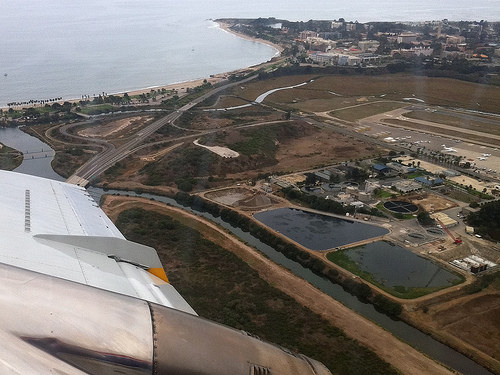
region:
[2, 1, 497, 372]
View from an airplane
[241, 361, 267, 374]
Vent on airplane wing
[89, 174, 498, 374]
Creek running down the city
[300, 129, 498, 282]
Group of buildings on the ground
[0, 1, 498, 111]
Large body of water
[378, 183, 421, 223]
Small black and white circle landing pad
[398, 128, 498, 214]
Group of trees on the ground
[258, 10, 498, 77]
Group of houses and buildings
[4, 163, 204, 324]
White wing of airplane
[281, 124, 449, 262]
Buildings on the ground.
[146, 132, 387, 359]
Water on the ground.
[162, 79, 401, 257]
Trees on the ground.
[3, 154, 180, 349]
Plane in the air.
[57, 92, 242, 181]
Road on the ground.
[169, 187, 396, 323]
Trees by the water.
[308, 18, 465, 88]
Town in the background.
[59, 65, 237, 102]
Beach by the water.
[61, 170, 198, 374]
Wing on the plane.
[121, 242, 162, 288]
Yellow part of the plane.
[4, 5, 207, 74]
calm water with no waves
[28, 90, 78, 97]
small waves near shore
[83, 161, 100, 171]
section of road for automobiles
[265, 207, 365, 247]
large pool of water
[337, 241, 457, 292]
large rectangular pool of water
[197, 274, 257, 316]
patch of earth missing grass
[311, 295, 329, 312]
dirt path near field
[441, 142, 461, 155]
parked airplane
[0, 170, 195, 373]
part of airplane in the air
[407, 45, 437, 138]
glare from window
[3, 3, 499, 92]
large body of water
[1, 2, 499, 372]
view from a plane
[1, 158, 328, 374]
side of a plane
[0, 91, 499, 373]
plane flying low to the ground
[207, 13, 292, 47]
land jutting out into the water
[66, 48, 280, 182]
asphalt road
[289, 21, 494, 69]
several buildings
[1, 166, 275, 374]
the plane is white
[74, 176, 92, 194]
corner of the plane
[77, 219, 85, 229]
black dot on the plane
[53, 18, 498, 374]
Aerial view of city on coastline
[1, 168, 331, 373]
Portion of airplane wing seen from inside airplane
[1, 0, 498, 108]
Large body of calm blue water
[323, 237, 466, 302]
Rectangular pond with rounded corners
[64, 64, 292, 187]
Multi-lane highway leading into and out of city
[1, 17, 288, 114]
Narrow beach along edge of water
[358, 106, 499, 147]
T-shaped runway at small airport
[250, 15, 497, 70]
Small city on point of land seen from the air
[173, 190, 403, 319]
Row of green trees along canal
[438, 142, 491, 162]
Group of small white airplanes on ground